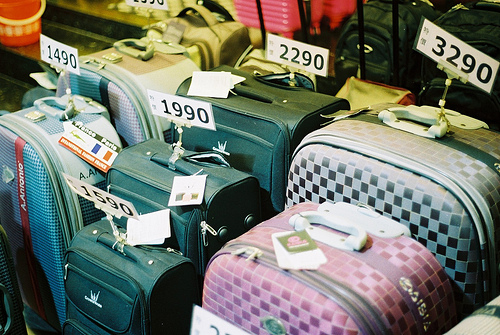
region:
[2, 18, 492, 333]
several pieces of luggage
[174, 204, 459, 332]
light purple and dark purple pattern on the luggage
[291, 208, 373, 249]
handle on top of the luggage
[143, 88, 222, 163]
sign on top of the suitcase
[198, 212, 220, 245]
silver zipper on the side of the case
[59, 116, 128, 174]
tag on the suitcase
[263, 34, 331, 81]
black numbers on a white background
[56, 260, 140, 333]
pocket on the front of the suitcase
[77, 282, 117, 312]
white design on the front of the pocket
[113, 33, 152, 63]
handle is laying down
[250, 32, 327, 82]
black and white labels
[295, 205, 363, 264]
white handle on luggage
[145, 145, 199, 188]
green handle on luggage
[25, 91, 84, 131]
blue handle on luggage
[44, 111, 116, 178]
orange and white tag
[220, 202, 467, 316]
pink and purple luggage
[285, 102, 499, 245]
black and grey luggage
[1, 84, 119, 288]
blue and white luggage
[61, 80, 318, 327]
row of green luggage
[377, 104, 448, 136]
the handle on the luggage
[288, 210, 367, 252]
the handle on the luggage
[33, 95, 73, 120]
the handle on the luggage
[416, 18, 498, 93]
the sign on the luggage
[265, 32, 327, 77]
the sign on the luggage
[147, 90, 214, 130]
the sign on the luggage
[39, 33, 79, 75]
the sign on the luggage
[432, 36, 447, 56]
the number 3 on the sign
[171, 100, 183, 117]
the number 9 on the sign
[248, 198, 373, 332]
pink piece of luggage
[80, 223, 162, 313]
black piece of luggage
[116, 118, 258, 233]
black piece of luggage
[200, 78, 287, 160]
black piece of luggage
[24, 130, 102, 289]
gray piece of luggage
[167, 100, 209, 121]
whtie sign on luggage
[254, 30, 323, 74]
whtie sign on luggage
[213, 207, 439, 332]
the bag is purple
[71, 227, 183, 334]
the bag is black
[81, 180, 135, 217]
1590 are the numbers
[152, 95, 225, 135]
1990 are the numbers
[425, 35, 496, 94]
3290 are the numbers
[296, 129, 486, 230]
the luggage is black and grey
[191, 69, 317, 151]
the bag is black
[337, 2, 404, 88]
the bag is black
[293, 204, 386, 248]
the handle is white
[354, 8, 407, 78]
the bag handle is black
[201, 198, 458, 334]
checkered purple suitcase with white handles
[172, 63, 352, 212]
black suitcase with white tags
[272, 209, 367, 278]
tags hanging off white handle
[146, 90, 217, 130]
Rectangle sign that says 1990.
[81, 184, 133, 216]
Black number 1590 on a card.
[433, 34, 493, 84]
Black number 3290 on a white card.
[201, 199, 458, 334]
Pink checkered luggage with white handles.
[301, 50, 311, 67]
Black number 9 between a 2 & 0 over a black luggage.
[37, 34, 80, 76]
White card with black 1490 on it.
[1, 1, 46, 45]
Orange bucket with yellow handle.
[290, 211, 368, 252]
White handle on top of pink checkered luggage.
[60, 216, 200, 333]
Small black luggage under the number 1590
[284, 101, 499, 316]
A grey and black checked suitcase under the number 3290